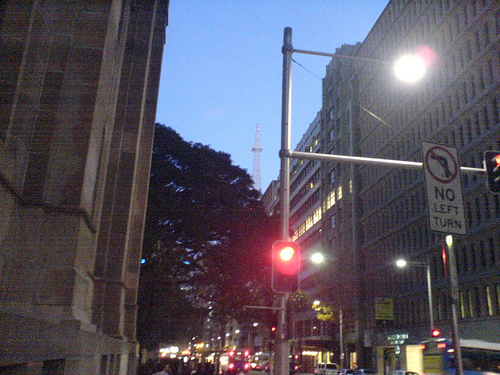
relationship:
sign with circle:
[423, 139, 471, 236] [418, 145, 462, 192]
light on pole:
[271, 240, 300, 294] [268, 25, 307, 370]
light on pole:
[394, 56, 426, 83] [298, 42, 396, 76]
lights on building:
[280, 178, 367, 260] [242, 0, 485, 350]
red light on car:
[272, 240, 300, 272] [220, 345, 251, 372]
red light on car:
[267, 322, 279, 333] [311, 352, 339, 372]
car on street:
[220, 345, 251, 372] [144, 329, 394, 370]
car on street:
[311, 352, 339, 372] [144, 329, 394, 370]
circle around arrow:
[426, 141, 460, 186] [418, 126, 479, 243]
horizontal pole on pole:
[280, 41, 427, 83] [270, 21, 292, 375]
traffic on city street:
[192, 339, 269, 374] [158, 332, 388, 372]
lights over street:
[147, 315, 342, 369] [134, 335, 393, 372]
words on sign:
[429, 183, 464, 232] [423, 139, 471, 236]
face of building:
[346, 0, 497, 328] [320, 0, 498, 343]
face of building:
[268, 117, 316, 322] [256, 109, 321, 351]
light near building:
[390, 51, 429, 86] [2, 2, 169, 372]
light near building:
[306, 251, 325, 267] [2, 2, 169, 372]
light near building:
[394, 256, 407, 271] [2, 2, 169, 372]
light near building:
[275, 246, 295, 263] [2, 2, 169, 372]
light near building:
[390, 51, 429, 86] [248, 1, 499, 362]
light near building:
[306, 251, 325, 267] [248, 1, 499, 362]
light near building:
[394, 256, 407, 271] [248, 1, 499, 362]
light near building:
[275, 246, 295, 263] [248, 1, 499, 362]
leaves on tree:
[195, 150, 203, 158] [151, 148, 266, 290]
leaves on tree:
[211, 177, 222, 190] [151, 148, 266, 290]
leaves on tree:
[205, 217, 235, 233] [151, 148, 266, 290]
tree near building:
[138, 122, 295, 353] [276, 110, 325, 373]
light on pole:
[390, 51, 429, 86] [260, 22, 301, 372]